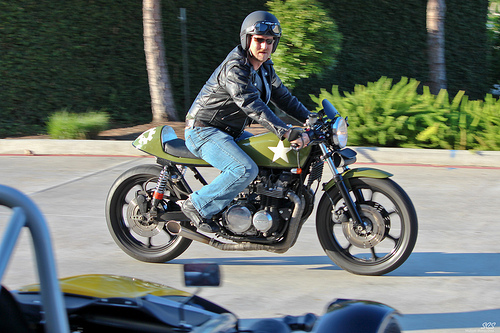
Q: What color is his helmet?
A: Dark black.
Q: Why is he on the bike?
A: To ride.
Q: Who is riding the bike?
A: A man.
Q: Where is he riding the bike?
A: Along the streets.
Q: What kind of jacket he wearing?
A: A leather.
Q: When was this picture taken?
A: In the day.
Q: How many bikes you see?
A: Only one.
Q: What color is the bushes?
A: There green.